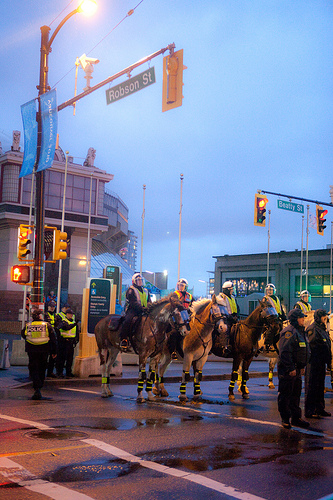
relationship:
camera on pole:
[75, 52, 100, 71] [34, 23, 48, 320]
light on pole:
[74, 0, 101, 23] [34, 23, 48, 320]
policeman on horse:
[123, 273, 149, 348] [95, 293, 184, 402]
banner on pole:
[17, 94, 38, 176] [34, 23, 48, 320]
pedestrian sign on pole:
[9, 263, 36, 286] [34, 23, 48, 320]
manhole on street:
[35, 422, 93, 444] [1, 365, 331, 499]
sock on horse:
[96, 364, 109, 391] [95, 293, 184, 402]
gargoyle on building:
[81, 146, 99, 168] [2, 149, 131, 367]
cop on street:
[25, 306, 56, 400] [1, 365, 331, 499]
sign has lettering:
[104, 67, 155, 105] [106, 73, 154, 102]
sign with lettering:
[104, 67, 155, 105] [106, 73, 154, 102]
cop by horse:
[25, 306, 56, 400] [95, 293, 184, 402]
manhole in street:
[35, 422, 93, 444] [1, 365, 331, 499]